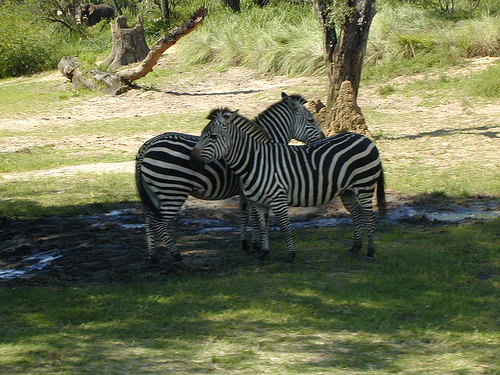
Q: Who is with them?
A: No one.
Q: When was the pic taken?
A: During the day.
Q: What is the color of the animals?
A: Black and white.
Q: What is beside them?
A: Tree.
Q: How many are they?
A: 2.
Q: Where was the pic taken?
A: Zoo.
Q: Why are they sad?
A: Hunger.